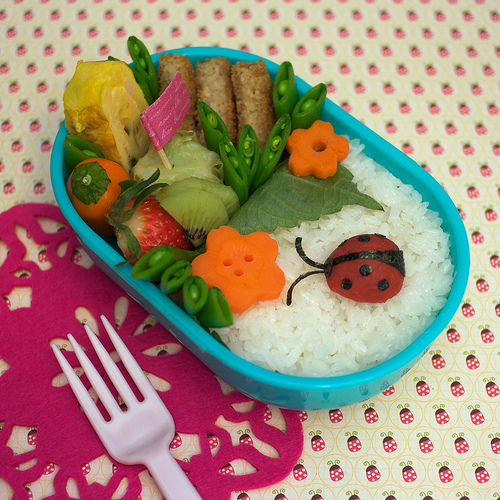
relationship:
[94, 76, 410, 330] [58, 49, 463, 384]
food in container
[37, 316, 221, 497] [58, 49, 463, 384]
fork near container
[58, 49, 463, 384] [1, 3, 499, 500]
container on table